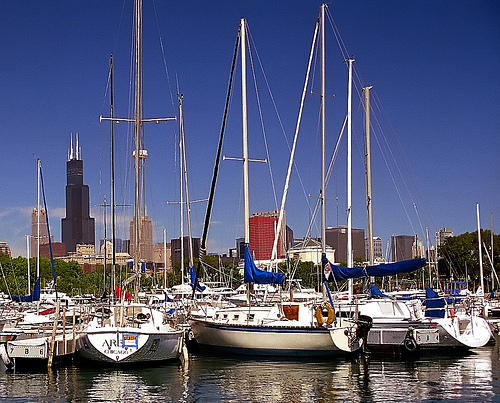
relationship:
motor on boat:
[343, 313, 373, 360] [186, 19, 368, 358]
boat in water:
[186, 19, 368, 358] [0, 343, 500, 401]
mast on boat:
[229, 17, 254, 290] [358, 295, 477, 352]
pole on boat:
[335, 53, 363, 314] [324, 296, 415, 364]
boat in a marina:
[186, 19, 368, 358] [2, 279, 494, 399]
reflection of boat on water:
[86, 370, 161, 402] [113, 365, 368, 382]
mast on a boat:
[202, 72, 331, 348] [176, 260, 384, 372]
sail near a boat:
[237, 240, 294, 293] [165, 245, 463, 373]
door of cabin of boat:
[204, 298, 314, 381] [184, 291, 376, 360]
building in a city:
[247, 207, 281, 260] [44, 155, 484, 244]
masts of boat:
[90, 311, 276, 399] [309, 296, 444, 359]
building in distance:
[40, 79, 127, 287] [13, 205, 465, 355]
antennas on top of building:
[62, 129, 92, 165] [52, 129, 103, 264]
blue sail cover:
[202, 228, 307, 322] [235, 248, 432, 277]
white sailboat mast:
[125, 166, 266, 340] [220, 12, 272, 311]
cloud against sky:
[0, 207, 160, 229] [1, 0, 498, 267]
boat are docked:
[79, 307, 190, 374] [10, 301, 339, 354]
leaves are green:
[4, 253, 105, 303] [20, 235, 75, 315]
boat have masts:
[191, 304, 362, 353] [125, 2, 146, 291]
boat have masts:
[475, 309, 497, 322] [125, 2, 146, 291]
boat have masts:
[369, 315, 491, 347] [125, 2, 146, 291]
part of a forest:
[22, 230, 83, 353] [2, 252, 181, 297]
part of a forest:
[6, 264, 80, 294] [0, 240, 115, 298]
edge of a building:
[9, 209, 155, 278] [30, 296, 72, 357]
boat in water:
[186, 19, 368, 358] [145, 344, 318, 403]